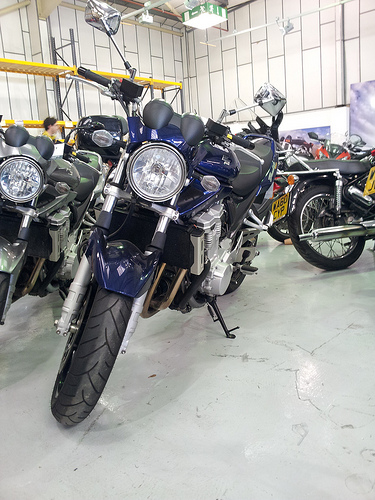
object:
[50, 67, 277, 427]
motorcycle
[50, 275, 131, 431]
tire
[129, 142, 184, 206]
headlight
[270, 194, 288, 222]
license plate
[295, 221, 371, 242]
muffler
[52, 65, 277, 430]
bike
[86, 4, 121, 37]
mirror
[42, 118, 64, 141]
man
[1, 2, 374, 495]
shop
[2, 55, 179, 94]
rack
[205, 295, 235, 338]
kickstand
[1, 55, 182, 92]
shelf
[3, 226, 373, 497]
floor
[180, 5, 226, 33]
light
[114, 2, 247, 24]
ceiling